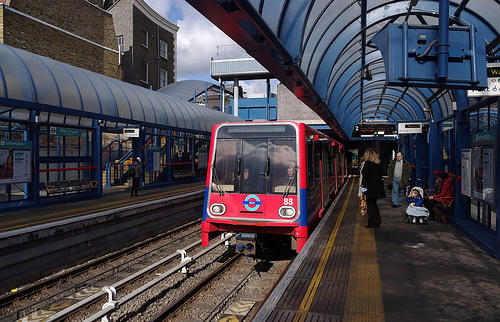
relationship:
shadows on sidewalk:
[327, 214, 434, 303] [318, 154, 475, 319]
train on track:
[203, 119, 351, 248] [119, 262, 273, 312]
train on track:
[203, 119, 351, 248] [169, 252, 296, 315]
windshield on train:
[214, 135, 299, 192] [195, 116, 351, 253]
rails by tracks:
[49, 232, 239, 319] [2, 216, 294, 320]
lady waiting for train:
[360, 148, 386, 228] [194, 110, 361, 253]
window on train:
[239, 140, 267, 192] [203, 119, 351, 248]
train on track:
[203, 119, 351, 248] [0, 213, 305, 320]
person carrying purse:
[123, 155, 143, 197] [125, 168, 137, 179]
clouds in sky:
[166, 13, 239, 61] [193, 70, 208, 76]